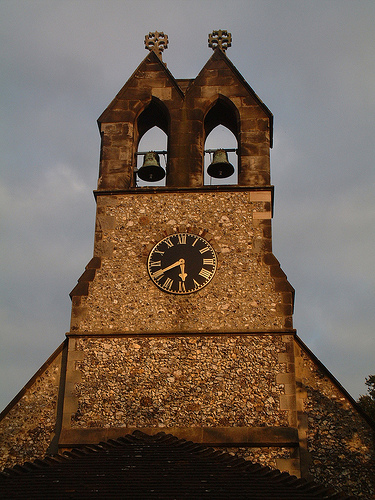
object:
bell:
[207, 149, 235, 179]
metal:
[199, 246, 210, 254]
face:
[148, 234, 215, 292]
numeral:
[203, 257, 215, 265]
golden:
[178, 259, 187, 282]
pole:
[203, 148, 237, 153]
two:
[136, 148, 236, 184]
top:
[94, 26, 274, 187]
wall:
[72, 333, 288, 433]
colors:
[212, 196, 240, 221]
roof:
[96, 31, 273, 120]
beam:
[135, 147, 238, 156]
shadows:
[288, 374, 369, 492]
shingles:
[92, 181, 275, 222]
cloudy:
[27, 22, 76, 56]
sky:
[234, 3, 373, 71]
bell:
[138, 150, 165, 182]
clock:
[146, 230, 219, 295]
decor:
[142, 30, 171, 57]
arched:
[202, 94, 243, 187]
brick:
[243, 110, 269, 180]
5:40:
[154, 258, 189, 286]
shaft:
[219, 171, 222, 175]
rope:
[209, 147, 212, 185]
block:
[245, 135, 271, 175]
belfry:
[0, 30, 375, 499]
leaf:
[363, 374, 374, 386]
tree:
[356, 367, 374, 412]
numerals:
[178, 236, 186, 243]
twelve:
[177, 232, 188, 245]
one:
[191, 237, 199, 247]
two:
[199, 247, 209, 255]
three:
[202, 258, 213, 266]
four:
[198, 267, 214, 279]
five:
[192, 278, 201, 288]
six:
[178, 281, 187, 293]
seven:
[162, 275, 174, 292]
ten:
[155, 247, 165, 256]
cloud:
[230, 9, 279, 46]